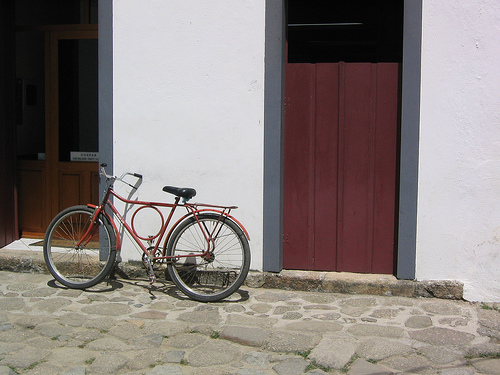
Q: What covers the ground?
A: Large stones.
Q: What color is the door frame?
A: Gray.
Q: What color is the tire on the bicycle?
A: Black and silver.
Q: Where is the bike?
A: Leaning on the building.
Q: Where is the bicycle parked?
A: Next to the wall.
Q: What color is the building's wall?
A: White.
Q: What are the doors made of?
A: Wood.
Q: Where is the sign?
A: In the door's window.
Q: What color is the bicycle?
A: Red.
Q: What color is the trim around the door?
A: Grey.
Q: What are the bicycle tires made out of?
A: Rubber.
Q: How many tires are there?
A: Two.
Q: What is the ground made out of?
A: Stone.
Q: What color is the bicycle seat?
A: Black.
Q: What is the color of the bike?
A: Red.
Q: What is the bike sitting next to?
A: The wall.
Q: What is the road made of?
A: Stones.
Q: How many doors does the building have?
A: Two.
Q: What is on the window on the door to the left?
A: A sign.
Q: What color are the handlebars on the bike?
A: Silver.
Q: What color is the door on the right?
A: Red.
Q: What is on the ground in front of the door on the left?
A: Doormat.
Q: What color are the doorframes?
A: Gray.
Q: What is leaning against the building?
A: Bicycle.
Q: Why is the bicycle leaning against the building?
A: So it doesn't fall over.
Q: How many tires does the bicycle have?
A: Two.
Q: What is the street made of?
A: Stone.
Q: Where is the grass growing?
A: In the spaces between the stones.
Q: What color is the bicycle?
A: Red.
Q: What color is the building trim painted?
A: Gray.